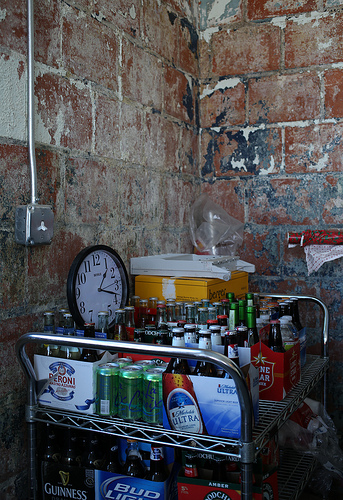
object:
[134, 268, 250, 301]
yellow box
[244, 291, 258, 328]
bottles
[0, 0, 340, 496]
photo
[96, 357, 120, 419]
cans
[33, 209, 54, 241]
light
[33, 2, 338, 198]
wall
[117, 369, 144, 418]
cans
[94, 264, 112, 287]
hand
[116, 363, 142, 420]
beer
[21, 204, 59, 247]
light switch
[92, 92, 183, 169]
brick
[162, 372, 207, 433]
beer bottle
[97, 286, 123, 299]
hands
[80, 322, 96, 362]
beers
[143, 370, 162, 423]
beer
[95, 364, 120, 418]
beer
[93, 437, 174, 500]
pack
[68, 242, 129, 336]
clock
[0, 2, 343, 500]
wall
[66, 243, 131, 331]
black frame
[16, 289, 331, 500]
metal cart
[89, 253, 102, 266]
number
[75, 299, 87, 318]
number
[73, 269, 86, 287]
number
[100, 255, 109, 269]
number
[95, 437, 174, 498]
bud beer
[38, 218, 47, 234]
switch